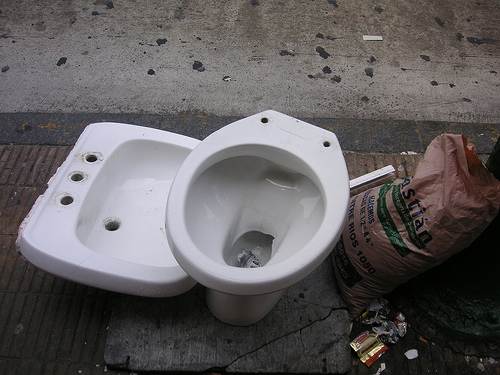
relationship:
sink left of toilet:
[18, 104, 200, 304] [157, 101, 367, 313]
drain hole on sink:
[100, 216, 123, 233] [18, 104, 200, 304]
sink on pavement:
[18, 104, 200, 304] [5, 107, 41, 189]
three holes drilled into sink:
[52, 144, 101, 210] [18, 104, 200, 304]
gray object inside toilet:
[231, 246, 260, 268] [157, 101, 367, 313]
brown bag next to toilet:
[342, 126, 493, 310] [157, 101, 367, 313]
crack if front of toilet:
[262, 227, 280, 249] [157, 101, 367, 313]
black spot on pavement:
[46, 51, 72, 67] [5, 107, 41, 189]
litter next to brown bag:
[343, 293, 423, 372] [342, 126, 493, 310]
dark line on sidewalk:
[28, 105, 496, 153] [6, 7, 499, 191]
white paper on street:
[361, 30, 381, 43] [6, 28, 495, 109]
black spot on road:
[46, 51, 72, 67] [15, 37, 486, 76]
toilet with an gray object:
[157, 101, 367, 313] [231, 246, 260, 268]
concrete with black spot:
[9, 36, 259, 86] [46, 51, 72, 67]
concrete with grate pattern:
[9, 36, 259, 86] [13, 145, 52, 173]